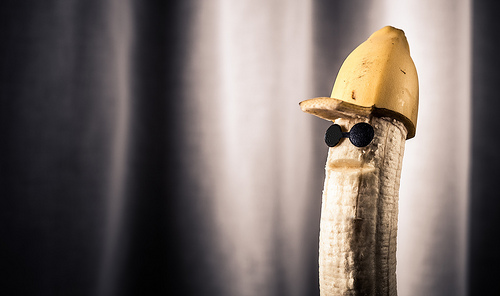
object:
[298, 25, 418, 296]
banana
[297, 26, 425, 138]
hat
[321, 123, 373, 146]
glasses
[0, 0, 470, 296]
curtain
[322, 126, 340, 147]
eye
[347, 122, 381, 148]
eye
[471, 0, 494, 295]
wall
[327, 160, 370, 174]
mouth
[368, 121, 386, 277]
line